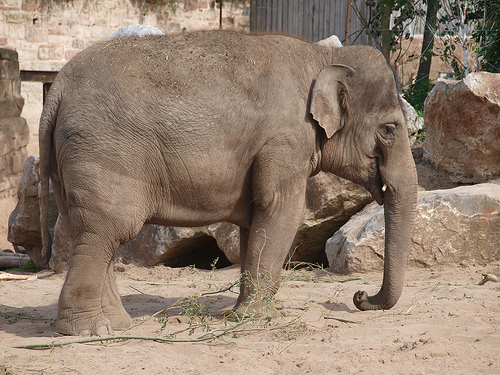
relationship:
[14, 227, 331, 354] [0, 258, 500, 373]
branch laying on ground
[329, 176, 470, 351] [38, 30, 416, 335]
trunk attached to elephant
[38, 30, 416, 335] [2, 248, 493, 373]
elephant in sand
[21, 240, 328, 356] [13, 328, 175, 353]
twig of a tree limb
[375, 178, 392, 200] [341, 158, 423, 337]
tusk on a trunk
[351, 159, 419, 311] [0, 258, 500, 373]
trunk on ground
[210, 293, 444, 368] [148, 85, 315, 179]
sand under elephant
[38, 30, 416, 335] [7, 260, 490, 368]
elephant standing on sand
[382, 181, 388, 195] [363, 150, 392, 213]
stick in mouth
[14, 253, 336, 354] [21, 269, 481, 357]
stick on ground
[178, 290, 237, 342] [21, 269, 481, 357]
leaves on ground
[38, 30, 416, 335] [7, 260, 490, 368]
elephant on sand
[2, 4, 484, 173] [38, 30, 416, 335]
wall behind elephant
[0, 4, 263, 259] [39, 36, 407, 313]
building behind elephant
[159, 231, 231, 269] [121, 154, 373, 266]
hole in rocks